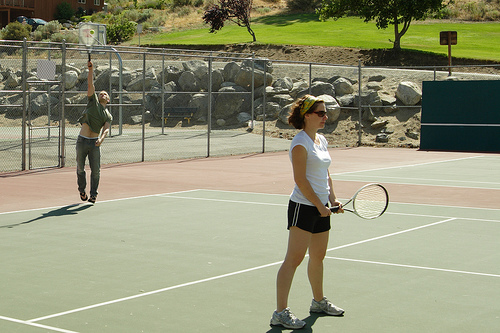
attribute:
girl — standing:
[273, 93, 343, 332]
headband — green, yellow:
[299, 97, 318, 111]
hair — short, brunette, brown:
[288, 97, 331, 128]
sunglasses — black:
[310, 109, 328, 117]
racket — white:
[336, 182, 390, 220]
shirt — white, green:
[292, 133, 332, 204]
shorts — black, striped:
[288, 200, 331, 232]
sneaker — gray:
[270, 310, 306, 326]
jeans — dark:
[76, 135, 100, 201]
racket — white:
[78, 22, 97, 60]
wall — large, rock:
[2, 61, 415, 125]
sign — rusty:
[440, 31, 457, 77]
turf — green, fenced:
[0, 188, 500, 332]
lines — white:
[2, 188, 500, 332]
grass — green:
[157, 19, 499, 47]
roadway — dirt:
[1, 55, 496, 77]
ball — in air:
[88, 27, 96, 38]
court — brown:
[0, 165, 294, 191]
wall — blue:
[422, 81, 500, 151]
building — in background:
[2, 0, 103, 14]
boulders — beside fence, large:
[4, 59, 359, 120]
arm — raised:
[85, 61, 95, 97]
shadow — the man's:
[2, 203, 94, 229]